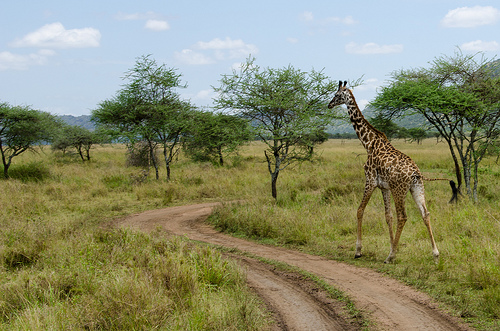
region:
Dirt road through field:
[131, 196, 473, 329]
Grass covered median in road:
[201, 246, 381, 325]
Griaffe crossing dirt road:
[321, 76, 459, 270]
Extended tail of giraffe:
[412, 170, 458, 205]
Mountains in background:
[0, 56, 495, 136]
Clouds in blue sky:
[7, 23, 103, 75]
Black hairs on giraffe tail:
[446, 180, 461, 206]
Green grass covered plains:
[11, 136, 491, 323]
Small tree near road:
[210, 53, 364, 204]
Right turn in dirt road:
[127, 189, 269, 244]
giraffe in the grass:
[317, 73, 444, 275]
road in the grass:
[158, 214, 443, 329]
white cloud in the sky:
[197, 34, 251, 53]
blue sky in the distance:
[271, 33, 346, 65]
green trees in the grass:
[98, 87, 260, 174]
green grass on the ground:
[9, 192, 89, 320]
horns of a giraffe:
[332, 75, 352, 91]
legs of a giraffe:
[355, 181, 446, 260]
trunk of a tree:
[446, 135, 489, 207]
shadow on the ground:
[11, 155, 58, 188]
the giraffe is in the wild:
[318, 78, 455, 281]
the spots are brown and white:
[339, 110, 434, 209]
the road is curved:
[150, 185, 290, 297]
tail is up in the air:
[415, 165, 482, 225]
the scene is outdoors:
[5, 21, 497, 328]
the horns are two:
[327, 71, 354, 96]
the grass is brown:
[59, 242, 184, 319]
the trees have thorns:
[245, 51, 323, 120]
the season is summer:
[15, 18, 489, 322]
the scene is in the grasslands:
[7, 21, 494, 330]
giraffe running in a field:
[323, 79, 456, 265]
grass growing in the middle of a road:
[243, 248, 379, 325]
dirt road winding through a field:
[113, 202, 474, 329]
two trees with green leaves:
[56, 122, 100, 167]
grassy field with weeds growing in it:
[2, 141, 496, 328]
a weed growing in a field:
[99, 261, 179, 329]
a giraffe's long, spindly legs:
[351, 169, 453, 264]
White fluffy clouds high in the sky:
[0, 18, 106, 74]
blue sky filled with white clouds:
[6, 0, 496, 114]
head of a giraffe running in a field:
[323, 79, 359, 118]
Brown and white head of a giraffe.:
[326, 79, 355, 110]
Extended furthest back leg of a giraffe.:
[410, 178, 441, 261]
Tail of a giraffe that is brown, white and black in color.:
[416, 174, 463, 204]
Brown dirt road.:
[121, 199, 465, 329]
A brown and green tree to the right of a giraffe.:
[363, 45, 498, 204]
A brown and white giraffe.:
[326, 78, 438, 262]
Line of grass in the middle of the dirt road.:
[207, 240, 364, 325]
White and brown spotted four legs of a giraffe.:
[355, 178, 440, 261]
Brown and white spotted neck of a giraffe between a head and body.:
[347, 96, 387, 148]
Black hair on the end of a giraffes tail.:
[448, 178, 465, 201]